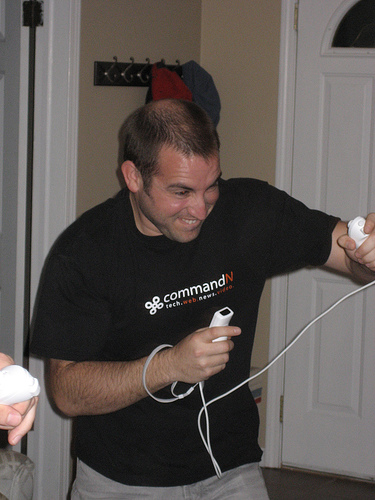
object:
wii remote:
[346, 215, 369, 249]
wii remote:
[209, 307, 235, 344]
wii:
[347, 216, 368, 249]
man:
[22, 98, 375, 500]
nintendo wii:
[143, 216, 375, 472]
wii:
[0, 360, 40, 408]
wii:
[208, 307, 235, 343]